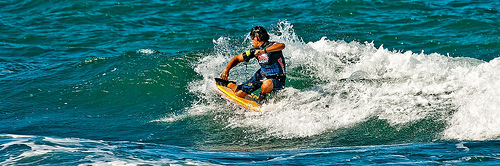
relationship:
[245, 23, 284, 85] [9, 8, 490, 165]
man in ocean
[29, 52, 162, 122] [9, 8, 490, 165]
waves in ocean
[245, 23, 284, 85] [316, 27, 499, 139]
man in water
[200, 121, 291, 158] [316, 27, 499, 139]
shadow in water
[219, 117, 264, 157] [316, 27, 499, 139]
bubbles in water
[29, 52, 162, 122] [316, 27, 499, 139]
waves in water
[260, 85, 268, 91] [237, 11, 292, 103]
knee of surfer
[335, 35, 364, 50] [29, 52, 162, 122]
breaks of waves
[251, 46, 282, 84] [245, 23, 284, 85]
wetsuit of man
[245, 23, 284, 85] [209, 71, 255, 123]
man on surfboard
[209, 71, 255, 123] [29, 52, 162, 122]
surfboard cutting through waves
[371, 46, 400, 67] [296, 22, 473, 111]
cap of wave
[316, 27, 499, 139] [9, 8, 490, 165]
water of ocean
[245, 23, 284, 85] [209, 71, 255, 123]
man riding surfboard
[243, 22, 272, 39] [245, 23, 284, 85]
hair of man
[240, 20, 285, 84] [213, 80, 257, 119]
boarder on board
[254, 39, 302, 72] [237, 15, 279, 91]
arm of rider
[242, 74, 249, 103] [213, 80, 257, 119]
knee touching board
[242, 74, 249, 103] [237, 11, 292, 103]
knee of surfer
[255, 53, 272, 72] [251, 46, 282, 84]
advertisements on wetsuit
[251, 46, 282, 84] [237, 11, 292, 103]
wetsuit of surfer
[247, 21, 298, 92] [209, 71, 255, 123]
person on surfboard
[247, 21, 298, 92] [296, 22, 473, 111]
person on wave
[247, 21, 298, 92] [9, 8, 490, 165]
person in ocean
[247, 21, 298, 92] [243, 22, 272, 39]
person has hair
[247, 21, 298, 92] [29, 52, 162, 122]
person riding waves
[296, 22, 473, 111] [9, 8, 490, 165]
wave of ocean